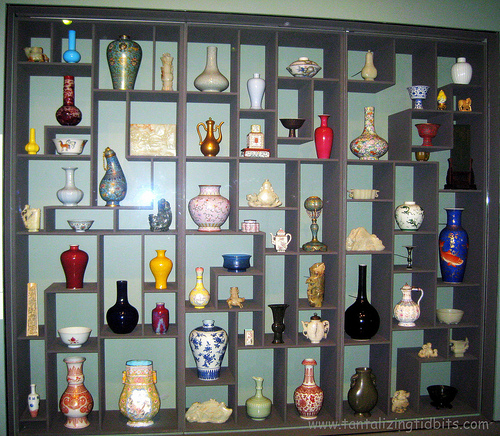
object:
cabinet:
[17, 18, 54, 66]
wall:
[0, 2, 500, 435]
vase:
[61, 30, 80, 65]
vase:
[106, 34, 144, 89]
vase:
[244, 70, 267, 112]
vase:
[313, 113, 334, 159]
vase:
[23, 128, 41, 154]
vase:
[106, 278, 138, 335]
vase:
[246, 374, 273, 420]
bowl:
[67, 218, 93, 232]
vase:
[344, 224, 387, 252]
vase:
[149, 248, 174, 290]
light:
[126, 181, 162, 215]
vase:
[187, 317, 230, 380]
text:
[303, 417, 491, 430]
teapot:
[195, 116, 224, 157]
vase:
[302, 262, 326, 308]